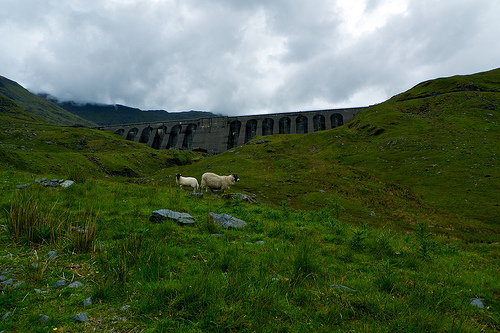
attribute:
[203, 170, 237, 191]
sheep — looking, white, standing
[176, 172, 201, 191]
sheep — looking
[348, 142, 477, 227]
grass — various colors, green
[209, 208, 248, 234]
rocks — small, large, gray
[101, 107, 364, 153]
bridge — large, gray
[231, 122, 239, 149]
arches — large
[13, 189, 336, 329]
grass — tall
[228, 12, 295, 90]
clouds — gray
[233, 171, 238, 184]
head — black